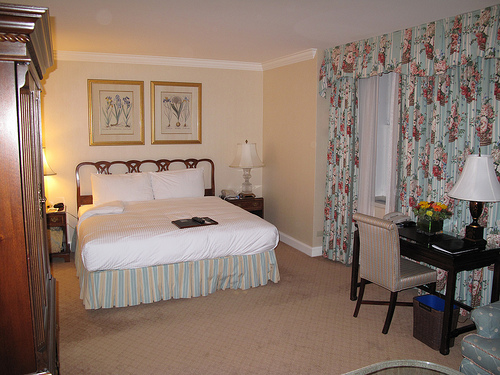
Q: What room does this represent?
A: It represents the bedroom.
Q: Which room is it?
A: It is a bedroom.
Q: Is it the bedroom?
A: Yes, it is the bedroom.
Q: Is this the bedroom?
A: Yes, it is the bedroom.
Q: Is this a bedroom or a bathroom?
A: It is a bedroom.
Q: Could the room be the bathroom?
A: No, it is the bedroom.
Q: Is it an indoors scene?
A: Yes, it is indoors.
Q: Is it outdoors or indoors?
A: It is indoors.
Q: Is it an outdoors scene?
A: No, it is indoors.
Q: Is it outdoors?
A: No, it is indoors.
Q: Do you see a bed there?
A: Yes, there is a bed.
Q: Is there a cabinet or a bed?
A: Yes, there is a bed.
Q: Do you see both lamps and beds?
A: Yes, there are both a bed and a lamp.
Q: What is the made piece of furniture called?
A: The piece of furniture is a bed.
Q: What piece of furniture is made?
A: The piece of furniture is a bed.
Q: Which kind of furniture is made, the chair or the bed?
A: The bed is made.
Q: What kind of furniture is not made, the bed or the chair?
A: The chair is not made.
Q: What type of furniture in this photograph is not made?
A: The furniture is a chair.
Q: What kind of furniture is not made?
A: The furniture is a chair.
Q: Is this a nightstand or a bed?
A: This is a bed.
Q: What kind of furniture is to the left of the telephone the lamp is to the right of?
A: The piece of furniture is a bed.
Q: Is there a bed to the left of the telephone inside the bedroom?
A: Yes, there is a bed to the left of the phone.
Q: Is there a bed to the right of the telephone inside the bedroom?
A: No, the bed is to the left of the telephone.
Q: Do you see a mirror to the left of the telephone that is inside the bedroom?
A: No, there is a bed to the left of the phone.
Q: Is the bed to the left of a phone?
A: Yes, the bed is to the left of a phone.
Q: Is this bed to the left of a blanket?
A: No, the bed is to the left of a phone.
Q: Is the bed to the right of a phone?
A: No, the bed is to the left of a phone.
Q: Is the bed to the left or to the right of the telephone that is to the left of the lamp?
A: The bed is to the left of the phone.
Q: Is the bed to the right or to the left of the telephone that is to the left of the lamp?
A: The bed is to the left of the phone.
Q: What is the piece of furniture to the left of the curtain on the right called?
A: The piece of furniture is a bed.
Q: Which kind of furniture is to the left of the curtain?
A: The piece of furniture is a bed.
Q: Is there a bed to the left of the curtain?
A: Yes, there is a bed to the left of the curtain.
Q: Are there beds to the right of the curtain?
A: No, the bed is to the left of the curtain.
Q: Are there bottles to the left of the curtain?
A: No, there is a bed to the left of the curtain.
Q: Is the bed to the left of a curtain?
A: Yes, the bed is to the left of a curtain.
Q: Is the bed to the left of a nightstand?
A: No, the bed is to the left of a curtain.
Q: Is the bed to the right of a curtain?
A: No, the bed is to the left of a curtain.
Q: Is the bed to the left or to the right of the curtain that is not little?
A: The bed is to the left of the curtain.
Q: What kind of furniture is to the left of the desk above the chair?
A: The piece of furniture is a bed.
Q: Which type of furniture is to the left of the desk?
A: The piece of furniture is a bed.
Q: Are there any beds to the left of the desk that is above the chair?
A: Yes, there is a bed to the left of the desk.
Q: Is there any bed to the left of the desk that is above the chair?
A: Yes, there is a bed to the left of the desk.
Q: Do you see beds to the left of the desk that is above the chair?
A: Yes, there is a bed to the left of the desk.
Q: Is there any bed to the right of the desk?
A: No, the bed is to the left of the desk.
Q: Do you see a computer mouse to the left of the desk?
A: No, there is a bed to the left of the desk.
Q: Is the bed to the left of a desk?
A: Yes, the bed is to the left of a desk.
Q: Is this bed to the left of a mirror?
A: No, the bed is to the left of a desk.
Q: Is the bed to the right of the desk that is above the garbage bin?
A: No, the bed is to the left of the desk.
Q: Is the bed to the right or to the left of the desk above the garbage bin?
A: The bed is to the left of the desk.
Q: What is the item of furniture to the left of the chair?
A: The piece of furniture is a bed.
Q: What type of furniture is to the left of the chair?
A: The piece of furniture is a bed.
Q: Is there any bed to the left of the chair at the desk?
A: Yes, there is a bed to the left of the chair.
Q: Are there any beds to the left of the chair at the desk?
A: Yes, there is a bed to the left of the chair.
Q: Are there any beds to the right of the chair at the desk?
A: No, the bed is to the left of the chair.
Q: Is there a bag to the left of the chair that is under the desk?
A: No, there is a bed to the left of the chair.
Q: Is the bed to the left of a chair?
A: Yes, the bed is to the left of a chair.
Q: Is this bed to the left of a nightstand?
A: No, the bed is to the left of a chair.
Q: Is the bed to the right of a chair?
A: No, the bed is to the left of a chair.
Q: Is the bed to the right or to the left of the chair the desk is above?
A: The bed is to the left of the chair.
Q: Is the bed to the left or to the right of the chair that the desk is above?
A: The bed is to the left of the chair.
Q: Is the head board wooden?
A: Yes, the head board is wooden.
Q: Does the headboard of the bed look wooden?
A: Yes, the head board is wooden.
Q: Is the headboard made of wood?
A: Yes, the headboard is made of wood.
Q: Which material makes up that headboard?
A: The headboard is made of wood.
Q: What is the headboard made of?
A: The headboard is made of wood.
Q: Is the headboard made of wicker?
A: No, the headboard is made of wood.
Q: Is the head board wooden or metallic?
A: The head board is wooden.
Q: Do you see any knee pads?
A: No, there are no knee pads.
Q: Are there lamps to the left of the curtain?
A: Yes, there are lamps to the left of the curtain.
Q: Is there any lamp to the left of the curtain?
A: Yes, there are lamps to the left of the curtain.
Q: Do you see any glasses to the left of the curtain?
A: No, there are lamps to the left of the curtain.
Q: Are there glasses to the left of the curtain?
A: No, there are lamps to the left of the curtain.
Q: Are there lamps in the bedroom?
A: Yes, there are lamps in the bedroom.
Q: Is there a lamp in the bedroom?
A: Yes, there are lamps in the bedroom.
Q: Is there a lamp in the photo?
A: Yes, there is a lamp.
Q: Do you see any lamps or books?
A: Yes, there is a lamp.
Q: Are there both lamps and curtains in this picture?
A: Yes, there are both a lamp and a curtain.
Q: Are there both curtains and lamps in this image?
A: Yes, there are both a lamp and a curtain.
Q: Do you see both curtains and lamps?
A: Yes, there are both a lamp and a curtain.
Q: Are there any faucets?
A: No, there are no faucets.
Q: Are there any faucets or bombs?
A: No, there are no faucets or bombs.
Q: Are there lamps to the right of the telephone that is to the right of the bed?
A: Yes, there is a lamp to the right of the phone.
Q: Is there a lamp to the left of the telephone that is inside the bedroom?
A: No, the lamp is to the right of the phone.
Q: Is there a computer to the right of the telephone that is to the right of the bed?
A: No, there is a lamp to the right of the telephone.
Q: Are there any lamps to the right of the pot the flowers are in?
A: Yes, there is a lamp to the right of the pot.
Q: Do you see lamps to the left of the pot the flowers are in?
A: No, the lamp is to the right of the pot.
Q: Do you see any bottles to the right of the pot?
A: No, there is a lamp to the right of the pot.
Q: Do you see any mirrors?
A: No, there are no mirrors.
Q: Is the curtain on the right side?
A: Yes, the curtain is on the right of the image.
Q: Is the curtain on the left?
A: No, the curtain is on the right of the image.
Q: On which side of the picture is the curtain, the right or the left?
A: The curtain is on the right of the image.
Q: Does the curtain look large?
A: Yes, the curtain is large.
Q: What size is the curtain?
A: The curtain is large.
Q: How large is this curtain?
A: The curtain is large.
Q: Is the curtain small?
A: No, the curtain is large.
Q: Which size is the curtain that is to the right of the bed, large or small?
A: The curtain is large.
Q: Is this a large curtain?
A: Yes, this is a large curtain.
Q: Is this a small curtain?
A: No, this is a large curtain.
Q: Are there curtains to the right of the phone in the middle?
A: Yes, there is a curtain to the right of the telephone.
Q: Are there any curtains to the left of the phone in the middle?
A: No, the curtain is to the right of the phone.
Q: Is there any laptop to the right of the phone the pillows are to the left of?
A: No, there is a curtain to the right of the telephone.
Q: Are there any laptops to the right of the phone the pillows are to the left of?
A: No, there is a curtain to the right of the telephone.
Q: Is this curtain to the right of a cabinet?
A: No, the curtain is to the right of a phone.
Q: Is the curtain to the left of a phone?
A: No, the curtain is to the right of a phone.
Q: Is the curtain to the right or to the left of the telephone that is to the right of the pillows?
A: The curtain is to the right of the telephone.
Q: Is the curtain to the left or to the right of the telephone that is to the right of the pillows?
A: The curtain is to the right of the telephone.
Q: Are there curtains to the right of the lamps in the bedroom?
A: Yes, there is a curtain to the right of the lamps.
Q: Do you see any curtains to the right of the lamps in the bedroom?
A: Yes, there is a curtain to the right of the lamps.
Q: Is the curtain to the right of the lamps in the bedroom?
A: Yes, the curtain is to the right of the lamps.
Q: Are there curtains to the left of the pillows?
A: No, the curtain is to the right of the pillows.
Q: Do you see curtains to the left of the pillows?
A: No, the curtain is to the right of the pillows.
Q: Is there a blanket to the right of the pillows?
A: No, there is a curtain to the right of the pillows.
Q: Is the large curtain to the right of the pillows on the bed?
A: Yes, the curtain is to the right of the pillows.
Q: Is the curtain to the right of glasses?
A: No, the curtain is to the right of the pillows.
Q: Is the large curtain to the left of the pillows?
A: No, the curtain is to the right of the pillows.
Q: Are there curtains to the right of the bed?
A: Yes, there is a curtain to the right of the bed.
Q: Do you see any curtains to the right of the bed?
A: Yes, there is a curtain to the right of the bed.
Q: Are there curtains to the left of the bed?
A: No, the curtain is to the right of the bed.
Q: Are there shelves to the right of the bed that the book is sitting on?
A: No, there is a curtain to the right of the bed.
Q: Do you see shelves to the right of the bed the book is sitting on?
A: No, there is a curtain to the right of the bed.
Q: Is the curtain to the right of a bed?
A: Yes, the curtain is to the right of a bed.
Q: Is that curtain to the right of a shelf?
A: No, the curtain is to the right of a bed.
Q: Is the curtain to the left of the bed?
A: No, the curtain is to the right of the bed.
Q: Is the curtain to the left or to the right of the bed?
A: The curtain is to the right of the bed.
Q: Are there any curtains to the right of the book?
A: Yes, there is a curtain to the right of the book.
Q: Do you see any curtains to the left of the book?
A: No, the curtain is to the right of the book.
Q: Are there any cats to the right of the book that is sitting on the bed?
A: No, there is a curtain to the right of the book.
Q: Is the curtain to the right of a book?
A: Yes, the curtain is to the right of a book.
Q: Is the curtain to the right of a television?
A: No, the curtain is to the right of a book.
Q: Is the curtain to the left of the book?
A: No, the curtain is to the right of the book.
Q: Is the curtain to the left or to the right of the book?
A: The curtain is to the right of the book.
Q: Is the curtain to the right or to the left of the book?
A: The curtain is to the right of the book.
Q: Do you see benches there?
A: No, there are no benches.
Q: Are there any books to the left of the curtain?
A: Yes, there is a book to the left of the curtain.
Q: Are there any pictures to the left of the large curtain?
A: No, there is a book to the left of the curtain.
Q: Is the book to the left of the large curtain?
A: Yes, the book is to the left of the curtain.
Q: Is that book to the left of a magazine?
A: No, the book is to the left of the curtain.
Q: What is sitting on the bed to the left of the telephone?
A: The book is sitting on the bed.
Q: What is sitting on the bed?
A: The book is sitting on the bed.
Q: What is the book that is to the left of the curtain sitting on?
A: The book is sitting on the bed.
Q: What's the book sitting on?
A: The book is sitting on the bed.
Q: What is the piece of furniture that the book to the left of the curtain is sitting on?
A: The piece of furniture is a bed.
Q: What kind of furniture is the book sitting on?
A: The book is sitting on the bed.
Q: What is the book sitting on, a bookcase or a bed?
A: The book is sitting on a bed.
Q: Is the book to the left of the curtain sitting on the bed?
A: Yes, the book is sitting on the bed.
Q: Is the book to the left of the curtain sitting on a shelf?
A: No, the book is sitting on the bed.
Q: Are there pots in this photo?
A: Yes, there is a pot.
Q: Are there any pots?
A: Yes, there is a pot.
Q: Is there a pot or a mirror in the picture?
A: Yes, there is a pot.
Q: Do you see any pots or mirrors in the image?
A: Yes, there is a pot.